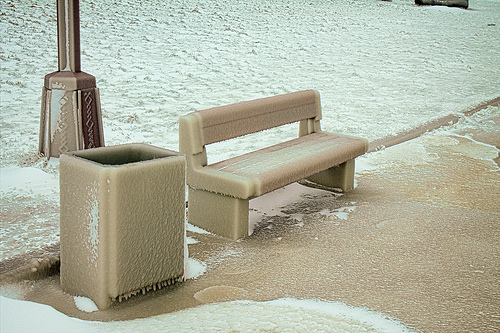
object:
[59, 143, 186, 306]
trash can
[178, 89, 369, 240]
bench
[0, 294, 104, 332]
snow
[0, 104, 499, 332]
sidewalk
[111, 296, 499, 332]
ice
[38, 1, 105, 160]
light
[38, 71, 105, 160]
base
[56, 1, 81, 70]
post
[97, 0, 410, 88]
snow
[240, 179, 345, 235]
snow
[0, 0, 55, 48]
grass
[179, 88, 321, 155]
top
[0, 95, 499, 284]
curb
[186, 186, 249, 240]
leg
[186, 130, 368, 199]
seat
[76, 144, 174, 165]
mouth